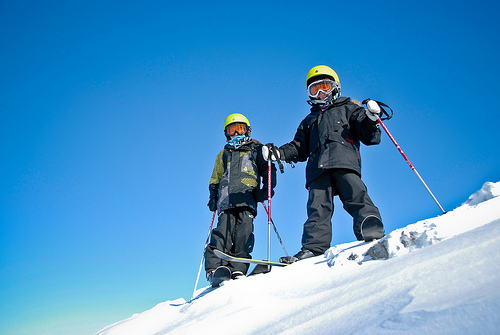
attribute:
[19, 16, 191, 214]
sky — blue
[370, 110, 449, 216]
pole — red, silver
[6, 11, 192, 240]
sky — blue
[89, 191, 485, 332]
hill — sloped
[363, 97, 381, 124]
mitten — white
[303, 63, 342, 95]
helmet — yellow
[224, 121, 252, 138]
goggles — orange tinted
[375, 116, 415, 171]
design — red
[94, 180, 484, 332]
snow — white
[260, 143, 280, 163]
glove — white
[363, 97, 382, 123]
glove — white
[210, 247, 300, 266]
ski — black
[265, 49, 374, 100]
helmets — yellow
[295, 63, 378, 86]
helmets — yellow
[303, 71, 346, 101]
goggles — orange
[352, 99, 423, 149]
mittens — white, staunch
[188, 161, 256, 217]
gloves — long, black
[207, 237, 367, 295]
ski — yellow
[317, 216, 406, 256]
ski — black